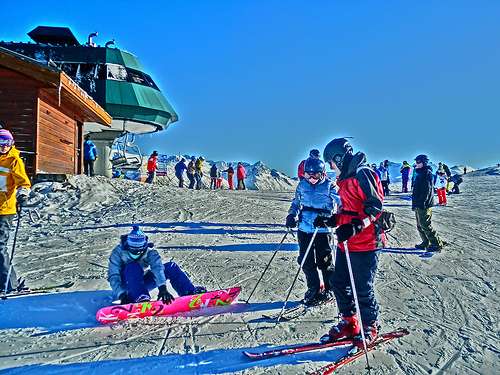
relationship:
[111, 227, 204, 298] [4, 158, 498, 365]
person in snow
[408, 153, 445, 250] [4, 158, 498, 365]
person in snow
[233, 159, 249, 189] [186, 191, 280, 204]
person standing in snow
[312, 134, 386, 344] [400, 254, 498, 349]
person standing in snow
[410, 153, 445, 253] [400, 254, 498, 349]
person standing in snow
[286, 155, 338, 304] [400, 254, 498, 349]
person standing in snow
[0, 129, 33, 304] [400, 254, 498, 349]
person standing in snow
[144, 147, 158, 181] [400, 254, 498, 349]
person standing in snow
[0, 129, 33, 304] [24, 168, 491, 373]
person standing in snow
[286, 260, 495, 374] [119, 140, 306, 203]
snow on hill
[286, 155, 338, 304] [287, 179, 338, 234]
person in a jacket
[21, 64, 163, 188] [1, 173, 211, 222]
building on hill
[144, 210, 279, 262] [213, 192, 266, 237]
shadow being cast on ground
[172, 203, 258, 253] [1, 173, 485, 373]
snow covers ground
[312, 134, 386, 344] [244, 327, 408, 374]
person standing on skis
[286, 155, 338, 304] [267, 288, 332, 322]
person standing on skis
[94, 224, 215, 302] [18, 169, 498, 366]
skateboarder on ground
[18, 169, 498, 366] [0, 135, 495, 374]
ground has snow